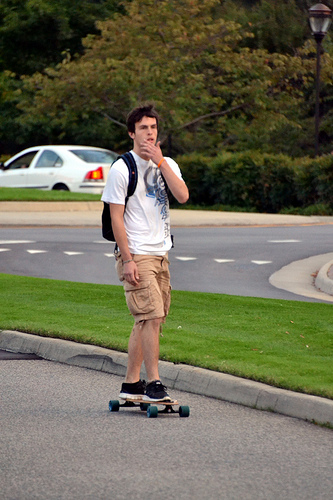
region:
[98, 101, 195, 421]
Young boy riding on skateboard.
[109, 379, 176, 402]
Young boy wearing black tennis shoes.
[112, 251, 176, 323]
Young boy dressed in tan shorts.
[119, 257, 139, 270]
Young wearing band around right wrist.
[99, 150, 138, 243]
Young boy carrying backpack on back.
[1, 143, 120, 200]
White car parked in parking space.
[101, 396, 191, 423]
Skateboard under boy's feet.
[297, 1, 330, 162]
Lamp post standing on other side of hedge.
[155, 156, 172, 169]
Young boy wearing orange band on left wrist.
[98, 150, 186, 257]
Young boy dressed in white t-shirt with gray and blue design on front.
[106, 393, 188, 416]
a white skateboard with blue wheels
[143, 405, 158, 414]
a blue skateboard wheel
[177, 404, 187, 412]
a blue skateboard wheel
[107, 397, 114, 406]
a blue skateboard wheel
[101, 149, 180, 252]
a person's white shirt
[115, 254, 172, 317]
a person's tan shorts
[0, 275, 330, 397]
a section of short grass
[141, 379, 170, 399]
a black and white shoe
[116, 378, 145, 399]
a black and white shoe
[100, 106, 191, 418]
a person riding a skateboard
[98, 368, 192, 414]
Man riding a stakeboard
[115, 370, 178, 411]
Man wearing black shoes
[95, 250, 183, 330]
man with brown shorts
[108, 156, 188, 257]
Man wearing white shirt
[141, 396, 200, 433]
green wheels on a skateboard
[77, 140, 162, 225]
Man wearing a backpack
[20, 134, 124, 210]
White car on the road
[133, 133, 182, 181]
Man with hand on face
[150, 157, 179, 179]
Man with band on wrist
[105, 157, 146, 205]
Man with black backpack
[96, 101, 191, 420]
a guy on a skateboard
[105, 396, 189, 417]
the wheels are blue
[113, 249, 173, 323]
the guy is wearing khaki shorts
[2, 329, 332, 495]
the road is gray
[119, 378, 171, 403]
the shoes are black and white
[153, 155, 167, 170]
a yellow wristband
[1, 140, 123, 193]
a white car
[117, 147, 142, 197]
the backpack strap is black and blue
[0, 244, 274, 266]
white triangles on the road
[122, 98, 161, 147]
the guy has dark hair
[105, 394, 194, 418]
skateboard on the street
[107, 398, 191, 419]
blue wheels on the skateboard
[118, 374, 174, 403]
black and white shoes on the man's feet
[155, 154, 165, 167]
orange wristband on the man's wrist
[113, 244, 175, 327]
brown cargo shorts on the man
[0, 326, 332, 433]
curb with a tire mark on it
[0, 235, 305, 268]
white lines in the street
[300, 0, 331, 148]
light pole behind the bushes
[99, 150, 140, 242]
black backpack on the man's back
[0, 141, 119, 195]
white car driving away